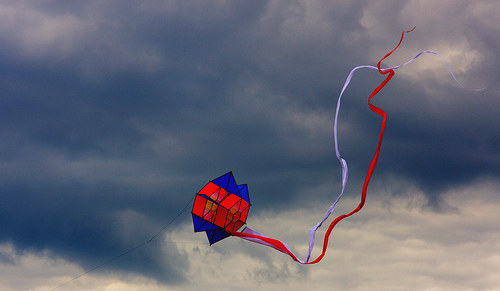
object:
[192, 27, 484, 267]
kite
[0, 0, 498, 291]
sky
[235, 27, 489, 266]
string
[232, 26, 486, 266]
tail